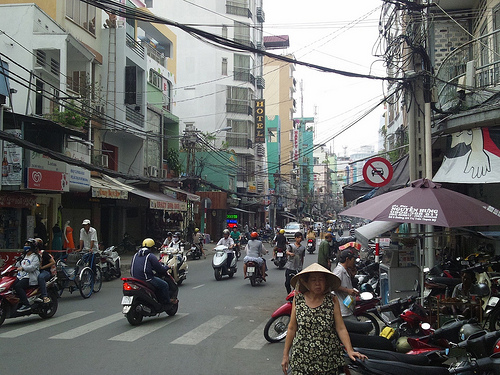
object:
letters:
[431, 209, 439, 218]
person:
[213, 227, 237, 257]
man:
[127, 235, 181, 307]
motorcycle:
[117, 266, 182, 328]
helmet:
[140, 235, 157, 250]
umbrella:
[335, 174, 499, 231]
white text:
[385, 203, 442, 224]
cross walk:
[0, 304, 295, 352]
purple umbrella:
[335, 179, 498, 229]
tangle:
[367, 0, 439, 115]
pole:
[401, 2, 418, 183]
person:
[13, 238, 41, 314]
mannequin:
[72, 218, 100, 284]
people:
[278, 261, 370, 375]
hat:
[288, 261, 342, 295]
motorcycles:
[210, 243, 240, 281]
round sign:
[360, 156, 394, 187]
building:
[136, 0, 271, 245]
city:
[0, 0, 499, 374]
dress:
[280, 292, 348, 374]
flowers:
[313, 339, 321, 347]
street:
[0, 229, 390, 374]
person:
[241, 230, 269, 288]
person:
[190, 226, 205, 258]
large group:
[278, 214, 370, 374]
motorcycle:
[240, 250, 269, 290]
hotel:
[252, 99, 266, 141]